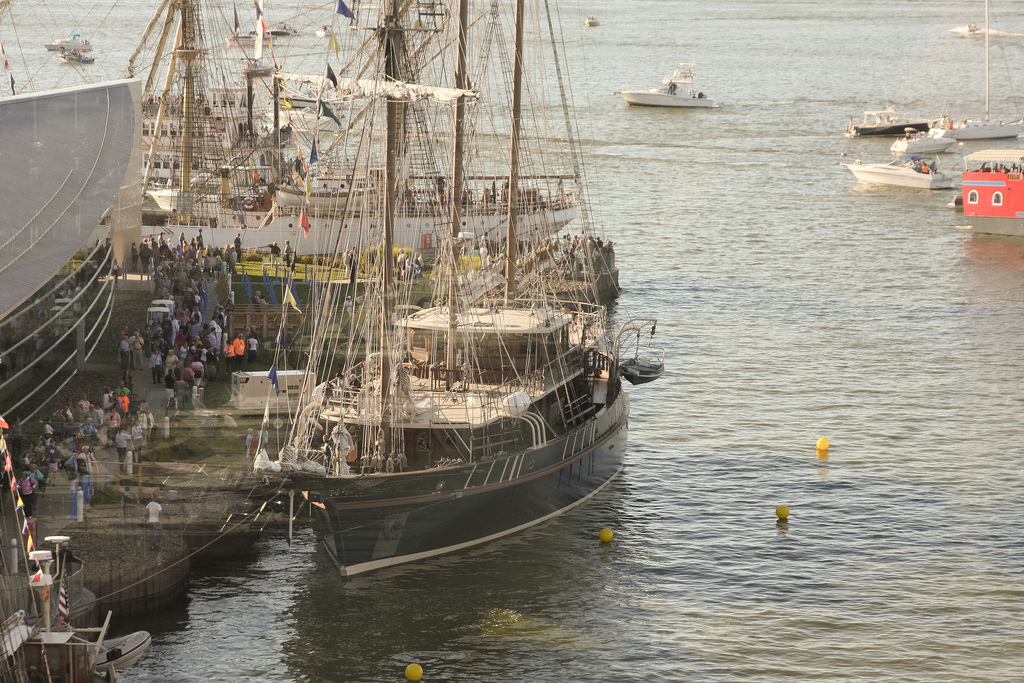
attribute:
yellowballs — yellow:
[757, 422, 833, 524]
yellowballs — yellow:
[589, 419, 845, 553]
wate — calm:
[691, 182, 958, 581]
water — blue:
[671, 153, 963, 571]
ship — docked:
[400, 194, 745, 635]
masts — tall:
[310, 44, 568, 412]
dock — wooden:
[84, 337, 337, 547]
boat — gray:
[232, 311, 641, 540]